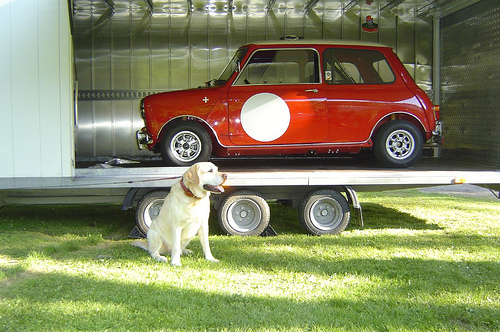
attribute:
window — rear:
[319, 50, 395, 85]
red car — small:
[133, 41, 448, 166]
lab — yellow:
[128, 152, 239, 272]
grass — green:
[398, 229, 485, 293]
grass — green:
[2, 185, 499, 330]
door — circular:
[225, 43, 329, 143]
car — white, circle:
[128, 33, 470, 179]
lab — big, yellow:
[136, 161, 227, 267]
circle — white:
[237, 89, 293, 141]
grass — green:
[272, 247, 399, 323]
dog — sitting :
[129, 160, 227, 266]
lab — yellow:
[136, 159, 222, 263]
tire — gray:
[134, 193, 172, 235]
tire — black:
[159, 121, 210, 164]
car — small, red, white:
[133, 29, 451, 168]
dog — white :
[142, 160, 226, 261]